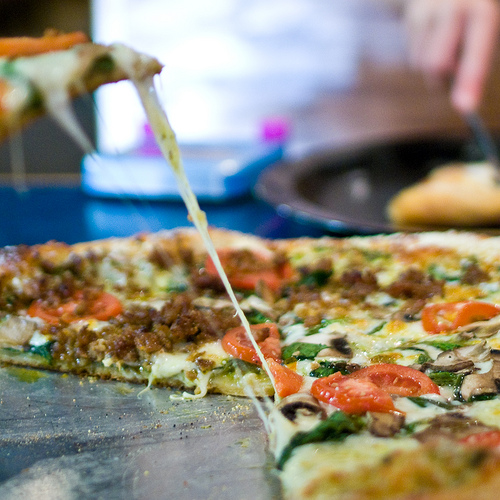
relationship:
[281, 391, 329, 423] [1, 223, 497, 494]
mushroom on pizza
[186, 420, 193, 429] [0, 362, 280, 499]
pizza crumb on metal plate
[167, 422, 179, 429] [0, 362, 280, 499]
pizza crumb on metal plate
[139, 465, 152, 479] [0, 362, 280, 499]
pizza crumb on metal plate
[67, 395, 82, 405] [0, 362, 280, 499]
pizza crumb on metal plate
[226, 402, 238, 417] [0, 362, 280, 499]
pizza crumb on metal plate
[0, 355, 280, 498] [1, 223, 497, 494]
metal plate under pizza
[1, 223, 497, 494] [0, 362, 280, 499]
pizza on metal plate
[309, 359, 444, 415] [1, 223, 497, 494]
tomato on pizza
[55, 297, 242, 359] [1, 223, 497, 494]
sausage on pizza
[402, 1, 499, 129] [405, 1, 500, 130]
person has hand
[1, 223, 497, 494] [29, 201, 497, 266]
pizza has crust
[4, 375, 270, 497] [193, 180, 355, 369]
empty space next pizza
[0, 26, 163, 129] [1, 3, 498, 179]
pizza in air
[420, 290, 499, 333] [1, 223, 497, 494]
tomato on pizza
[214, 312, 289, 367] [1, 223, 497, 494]
tomato on pizza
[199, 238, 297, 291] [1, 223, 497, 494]
tomato on pizza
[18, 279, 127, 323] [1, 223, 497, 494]
tomato on pizza